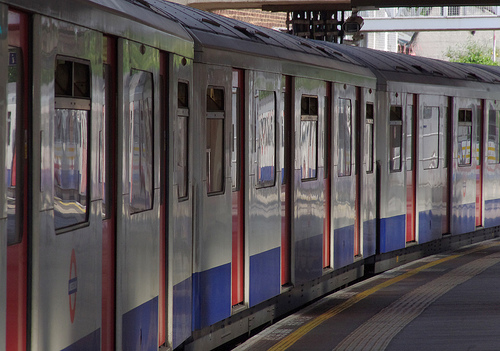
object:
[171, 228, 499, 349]
curve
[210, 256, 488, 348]
track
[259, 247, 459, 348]
track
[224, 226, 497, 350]
sidewalk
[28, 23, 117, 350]
door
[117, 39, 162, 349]
door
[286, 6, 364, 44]
equipment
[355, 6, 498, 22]
building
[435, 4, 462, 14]
window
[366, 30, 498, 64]
siding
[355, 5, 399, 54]
building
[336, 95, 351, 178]
window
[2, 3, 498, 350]
subway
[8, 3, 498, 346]
train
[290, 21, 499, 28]
support beam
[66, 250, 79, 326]
logo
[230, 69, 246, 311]
doors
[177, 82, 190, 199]
window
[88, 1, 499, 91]
roof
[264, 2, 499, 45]
beam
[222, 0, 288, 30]
building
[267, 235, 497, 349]
stripe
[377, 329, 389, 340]
brick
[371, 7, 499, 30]
subway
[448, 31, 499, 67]
tree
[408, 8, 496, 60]
buiding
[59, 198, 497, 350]
line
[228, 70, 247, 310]
door